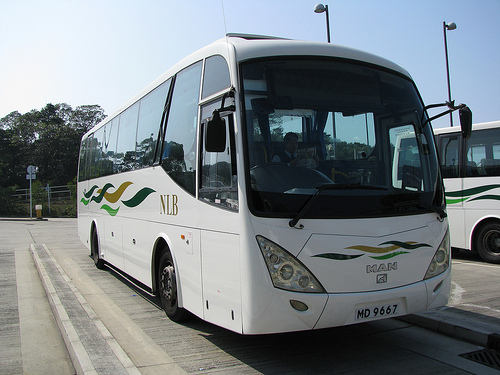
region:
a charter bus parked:
[52, 39, 474, 340]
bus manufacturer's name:
[357, 260, 408, 282]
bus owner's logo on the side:
[145, 190, 187, 222]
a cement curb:
[22, 234, 107, 374]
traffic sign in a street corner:
[25, 156, 46, 221]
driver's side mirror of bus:
[423, 86, 475, 141]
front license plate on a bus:
[354, 299, 411, 321]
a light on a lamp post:
[431, 12, 464, 42]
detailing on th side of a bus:
[78, 179, 161, 219]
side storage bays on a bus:
[100, 215, 154, 269]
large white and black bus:
[40, 49, 431, 291]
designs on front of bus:
[312, 228, 431, 260]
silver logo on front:
[361, 263, 406, 289]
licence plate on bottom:
[357, 303, 406, 325]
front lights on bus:
[260, 234, 318, 290]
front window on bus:
[237, 70, 431, 215]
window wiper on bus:
[280, 188, 329, 230]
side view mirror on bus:
[206, 108, 231, 145]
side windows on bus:
[57, 117, 203, 185]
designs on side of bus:
[57, 180, 140, 213]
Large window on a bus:
[240, 56, 424, 206]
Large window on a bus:
[202, 62, 231, 212]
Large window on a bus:
[163, 74, 194, 188]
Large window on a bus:
[134, 97, 163, 171]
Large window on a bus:
[111, 109, 148, 167]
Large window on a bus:
[69, 124, 139, 179]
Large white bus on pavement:
[40, 81, 415, 369]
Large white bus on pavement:
[393, 119, 474, 206]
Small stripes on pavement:
[15, 233, 126, 373]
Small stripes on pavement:
[453, 254, 495, 281]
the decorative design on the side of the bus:
[62, 181, 157, 214]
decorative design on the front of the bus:
[332, 227, 458, 262]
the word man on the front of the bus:
[364, 260, 409, 274]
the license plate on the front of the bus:
[348, 303, 411, 325]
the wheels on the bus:
[73, 214, 211, 326]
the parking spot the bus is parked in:
[49, 213, 486, 370]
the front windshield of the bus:
[243, 63, 438, 214]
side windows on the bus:
[69, 76, 230, 182]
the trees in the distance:
[12, 106, 107, 206]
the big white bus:
[58, 34, 454, 329]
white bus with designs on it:
[78, 180, 154, 217]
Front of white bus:
[228, 39, 450, 336]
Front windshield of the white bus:
[236, 56, 444, 217]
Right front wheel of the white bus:
[151, 240, 184, 321]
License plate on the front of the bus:
[351, 300, 400, 323]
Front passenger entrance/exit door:
[197, 85, 249, 335]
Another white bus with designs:
[392, 122, 497, 262]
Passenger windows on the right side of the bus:
[72, 55, 202, 201]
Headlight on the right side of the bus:
[253, 232, 328, 295]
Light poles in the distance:
[311, 0, 457, 126]